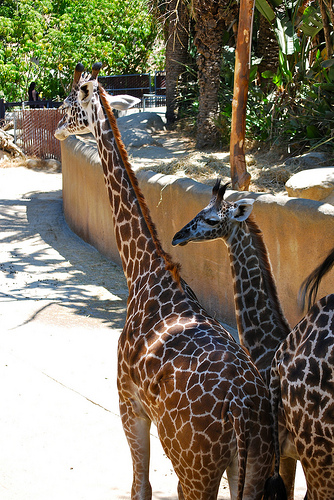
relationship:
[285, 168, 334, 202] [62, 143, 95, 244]
rock above wall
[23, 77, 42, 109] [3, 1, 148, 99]
person standing near trees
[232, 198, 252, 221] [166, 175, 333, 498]
ear of giraffe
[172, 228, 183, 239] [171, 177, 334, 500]
nose of giraffe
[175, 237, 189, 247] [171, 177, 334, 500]
mouth of giraffe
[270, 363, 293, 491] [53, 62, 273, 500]
tail of giraffe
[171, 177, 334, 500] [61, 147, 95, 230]
giraffe besides wall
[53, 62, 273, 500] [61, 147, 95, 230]
giraffe besides wall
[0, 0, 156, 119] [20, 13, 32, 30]
trees have leaves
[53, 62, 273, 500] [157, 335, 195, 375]
giraffe has spots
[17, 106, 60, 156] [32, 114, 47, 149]
fence has lattice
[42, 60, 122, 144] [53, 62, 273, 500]
head on giraffe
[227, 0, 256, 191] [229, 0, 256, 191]
tree has tree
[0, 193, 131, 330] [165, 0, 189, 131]
shadows cast by tree trunk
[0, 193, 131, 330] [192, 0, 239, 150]
shadows cast by palm tree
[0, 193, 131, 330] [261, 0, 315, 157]
shadows cast by tree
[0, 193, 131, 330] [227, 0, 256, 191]
shadows cast by tree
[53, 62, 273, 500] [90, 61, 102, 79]
giraffe has horn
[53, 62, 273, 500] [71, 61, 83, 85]
giraffe has horn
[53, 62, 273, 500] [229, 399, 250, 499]
giraffe has tail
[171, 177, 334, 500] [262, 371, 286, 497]
giraffe has tail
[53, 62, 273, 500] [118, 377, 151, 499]
giraffe has leg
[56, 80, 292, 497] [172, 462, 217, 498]
giraffe has back/left leg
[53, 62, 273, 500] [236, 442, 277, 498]
giraffe has leg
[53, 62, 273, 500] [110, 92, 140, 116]
giraffe has ear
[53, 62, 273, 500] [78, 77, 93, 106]
giraffe has ear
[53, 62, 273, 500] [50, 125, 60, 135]
giraffe has nose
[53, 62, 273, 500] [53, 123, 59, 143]
giraffe has mouth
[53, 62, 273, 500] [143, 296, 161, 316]
giraffe has spot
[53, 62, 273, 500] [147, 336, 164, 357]
giraffe has spot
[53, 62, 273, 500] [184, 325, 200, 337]
giraffe has spot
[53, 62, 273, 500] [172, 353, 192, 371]
giraffe has spot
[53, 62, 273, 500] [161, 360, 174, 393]
giraffe has spot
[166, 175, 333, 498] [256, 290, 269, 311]
giraffe has spot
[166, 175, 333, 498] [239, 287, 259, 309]
giraffe has spot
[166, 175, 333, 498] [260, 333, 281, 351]
giraffe has spot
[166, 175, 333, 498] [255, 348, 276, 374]
giraffe has spot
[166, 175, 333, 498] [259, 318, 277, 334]
giraffe has spot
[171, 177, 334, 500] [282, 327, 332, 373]
giraffe has brown spots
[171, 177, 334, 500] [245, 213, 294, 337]
giraffe has mane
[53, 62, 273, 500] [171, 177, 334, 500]
giraffe standing next to giraffe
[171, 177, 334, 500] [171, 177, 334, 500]
giraffe standing next to giraffe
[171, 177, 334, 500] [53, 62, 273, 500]
giraffe standing next to giraffe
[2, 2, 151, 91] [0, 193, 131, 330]
trees casting shadows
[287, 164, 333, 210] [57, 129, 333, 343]
rock on top of wall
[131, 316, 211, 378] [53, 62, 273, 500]
spots on side of giraffe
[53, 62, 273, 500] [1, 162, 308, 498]
giraffe walking on ground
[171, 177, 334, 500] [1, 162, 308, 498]
giraffe walking on ground